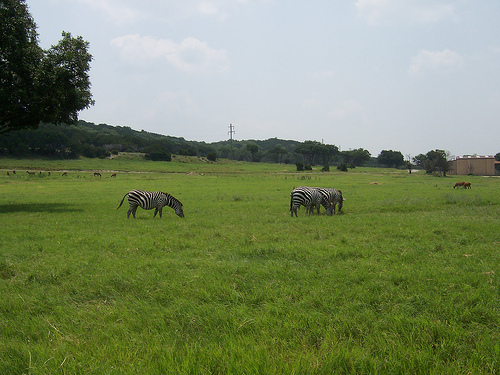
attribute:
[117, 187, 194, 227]
zebra — grazing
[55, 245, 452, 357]
grass — green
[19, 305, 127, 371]
grass —  brown, slivers 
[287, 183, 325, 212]
zebra — grazing 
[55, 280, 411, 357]
grass — grazing 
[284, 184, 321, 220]
zebra — grazing 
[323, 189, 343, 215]
zebra — grazing 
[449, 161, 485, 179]
building — white, tan , long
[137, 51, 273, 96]
cloud — white, large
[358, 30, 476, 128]
cloud — white, large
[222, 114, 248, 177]
pole — utility, brown, tall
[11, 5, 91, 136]
trees — tall, green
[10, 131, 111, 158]
trees — smaller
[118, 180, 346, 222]
zebras — bunch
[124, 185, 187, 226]
zebra — bent , over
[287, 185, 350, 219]
zebras —  grazing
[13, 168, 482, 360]
field —  grassy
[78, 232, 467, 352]
grass — medium , height 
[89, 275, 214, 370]
grass — brown , green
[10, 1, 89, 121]
tree — tall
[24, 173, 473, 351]
field — open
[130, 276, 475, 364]
grass — tall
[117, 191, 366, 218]
zebras — grazing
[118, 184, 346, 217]
zebras — striped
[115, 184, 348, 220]
zebras — white and black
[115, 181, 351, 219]
zebras — grouped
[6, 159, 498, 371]
open field — large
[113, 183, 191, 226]
zebra — eating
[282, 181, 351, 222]
zebra — grouped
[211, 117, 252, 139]
pole — telephone , center 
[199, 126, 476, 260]
animals — brown 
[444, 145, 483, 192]
shed — tan , right far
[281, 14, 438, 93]
cloud — center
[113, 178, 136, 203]
tail — left zebra's 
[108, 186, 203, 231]
head — left zebra's 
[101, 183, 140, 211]
tail — zebra's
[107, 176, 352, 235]
zebras — middle 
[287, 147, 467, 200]
horse — distance, brown 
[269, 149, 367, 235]
animals — distance, group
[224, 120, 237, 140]
post — wooden 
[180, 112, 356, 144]
lines — cable 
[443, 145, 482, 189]
building — tan 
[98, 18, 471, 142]
sky — grey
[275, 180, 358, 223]
zebra — grazing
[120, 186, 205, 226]
zebra — grazing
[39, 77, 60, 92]
leaves — green 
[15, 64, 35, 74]
leaves — green 